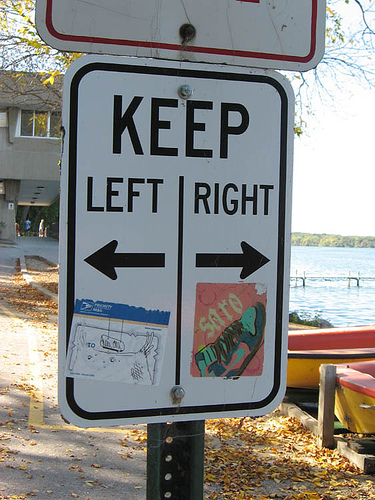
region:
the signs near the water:
[34, 0, 325, 428]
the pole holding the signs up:
[146, 420, 203, 499]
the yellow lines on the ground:
[0, 302, 146, 435]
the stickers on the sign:
[64, 283, 267, 386]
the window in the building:
[20, 110, 62, 139]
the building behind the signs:
[0, 69, 63, 245]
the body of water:
[288, 243, 373, 327]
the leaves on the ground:
[0, 253, 374, 498]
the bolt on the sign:
[178, 83, 191, 100]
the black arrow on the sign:
[195, 241, 270, 279]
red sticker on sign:
[190, 294, 301, 398]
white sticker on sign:
[87, 312, 178, 393]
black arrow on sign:
[97, 243, 176, 284]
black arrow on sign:
[181, 248, 285, 271]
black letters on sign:
[91, 178, 169, 226]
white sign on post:
[46, 163, 336, 449]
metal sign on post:
[50, 239, 312, 470]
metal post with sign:
[65, 389, 277, 483]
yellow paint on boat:
[294, 327, 345, 426]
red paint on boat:
[293, 317, 338, 359]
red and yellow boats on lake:
[268, 321, 372, 442]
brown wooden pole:
[315, 364, 340, 447]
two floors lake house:
[2, 69, 100, 272]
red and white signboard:
[35, 0, 325, 71]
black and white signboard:
[59, 56, 289, 420]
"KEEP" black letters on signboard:
[112, 96, 248, 164]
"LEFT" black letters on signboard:
[85, 174, 165, 214]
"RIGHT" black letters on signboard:
[194, 178, 275, 218]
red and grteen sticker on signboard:
[190, 283, 267, 376]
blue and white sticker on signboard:
[66, 294, 171, 380]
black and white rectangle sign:
[52, 62, 318, 394]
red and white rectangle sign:
[31, 1, 370, 99]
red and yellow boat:
[279, 314, 373, 407]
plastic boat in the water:
[331, 353, 374, 449]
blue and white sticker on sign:
[49, 287, 160, 399]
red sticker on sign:
[186, 270, 266, 424]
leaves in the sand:
[219, 414, 326, 498]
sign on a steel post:
[126, 401, 213, 487]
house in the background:
[6, 74, 63, 263]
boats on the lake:
[305, 249, 374, 429]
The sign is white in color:
[45, 50, 300, 436]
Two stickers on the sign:
[62, 258, 272, 400]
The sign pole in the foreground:
[137, 410, 218, 496]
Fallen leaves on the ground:
[207, 396, 353, 497]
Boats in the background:
[290, 312, 374, 433]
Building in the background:
[0, 67, 67, 251]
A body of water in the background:
[292, 244, 374, 326]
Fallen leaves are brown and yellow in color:
[198, 411, 361, 497]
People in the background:
[14, 215, 52, 237]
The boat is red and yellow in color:
[287, 324, 373, 440]